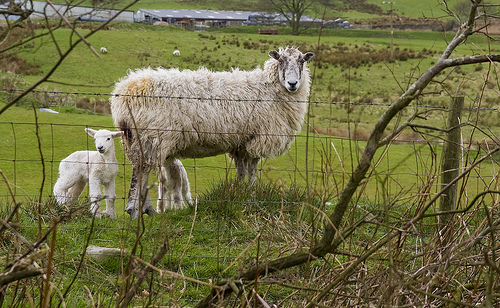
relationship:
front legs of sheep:
[226, 150, 261, 187] [107, 45, 313, 217]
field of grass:
[15, 21, 467, 300] [2, 3, 496, 295]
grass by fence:
[195, 195, 374, 237] [37, 97, 473, 239]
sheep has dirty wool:
[107, 45, 313, 217] [121, 71, 161, 108]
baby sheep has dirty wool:
[53, 128, 123, 218] [121, 71, 161, 108]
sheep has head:
[107, 45, 313, 217] [268, 44, 313, 95]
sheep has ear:
[107, 45, 313, 217] [302, 49, 317, 63]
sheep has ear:
[107, 45, 313, 217] [268, 50, 281, 60]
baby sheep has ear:
[53, 128, 123, 218] [110, 130, 124, 140]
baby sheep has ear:
[53, 128, 123, 218] [84, 123, 95, 136]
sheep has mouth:
[109, 48, 315, 221] [271, 62, 313, 92]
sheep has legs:
[107, 45, 313, 217] [120, 130, 200, 222]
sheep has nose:
[109, 48, 315, 221] [287, 80, 298, 88]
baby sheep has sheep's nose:
[53, 128, 123, 218] [95, 142, 106, 149]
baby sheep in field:
[53, 128, 123, 218] [2, 3, 499, 252]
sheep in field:
[109, 48, 315, 221] [2, 3, 499, 252]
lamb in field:
[157, 158, 197, 214] [2, 3, 499, 252]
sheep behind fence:
[107, 45, 313, 217] [383, 126, 441, 213]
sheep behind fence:
[109, 48, 315, 221] [0, 88, 435, 278]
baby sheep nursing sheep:
[53, 128, 123, 218] [101, 35, 323, 207]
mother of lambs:
[109, 48, 313, 219] [43, 117, 190, 209]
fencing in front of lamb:
[1, 93, 499, 306] [50, 124, 125, 218]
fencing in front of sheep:
[1, 93, 499, 306] [107, 45, 313, 217]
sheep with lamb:
[107, 45, 313, 217] [50, 124, 125, 218]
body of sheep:
[113, 70, 310, 155] [61, 39, 363, 210]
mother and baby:
[111, 45, 314, 214] [51, 126, 127, 216]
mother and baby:
[111, 45, 314, 214] [153, 157, 193, 216]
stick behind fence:
[199, 0, 499, 305] [15, 94, 462, 258]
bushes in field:
[292, 26, 470, 80] [3, 25, 498, 219]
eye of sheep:
[275, 52, 288, 66] [68, 17, 353, 215]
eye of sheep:
[295, 58, 304, 68] [68, 17, 353, 215]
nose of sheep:
[275, 63, 309, 101] [107, 45, 313, 217]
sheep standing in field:
[107, 45, 313, 217] [3, 25, 498, 219]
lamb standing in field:
[157, 158, 197, 214] [3, 25, 498, 219]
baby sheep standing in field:
[53, 128, 123, 218] [3, 25, 498, 219]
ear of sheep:
[300, 47, 319, 64] [107, 45, 313, 217]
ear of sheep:
[264, 48, 283, 65] [107, 45, 313, 217]